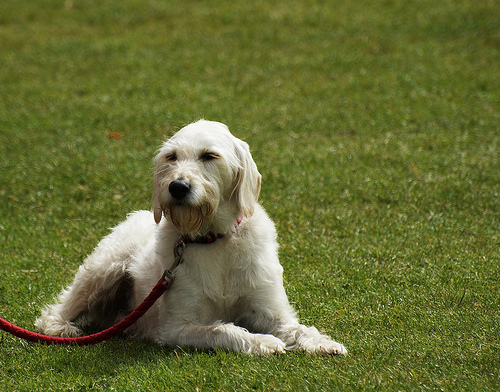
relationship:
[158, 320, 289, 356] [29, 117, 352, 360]
front leg of a dog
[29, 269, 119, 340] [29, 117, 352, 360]
back leg of a dog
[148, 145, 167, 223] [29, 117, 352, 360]
right ear of a dog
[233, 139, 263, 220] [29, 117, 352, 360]
left ear of a dog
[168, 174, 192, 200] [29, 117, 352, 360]
nose on front of dog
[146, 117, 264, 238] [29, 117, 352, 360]
head of a dog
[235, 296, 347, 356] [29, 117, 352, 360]
leg of a dog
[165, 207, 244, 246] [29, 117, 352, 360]
collar of a dog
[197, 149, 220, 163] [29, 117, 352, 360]
eye of a dog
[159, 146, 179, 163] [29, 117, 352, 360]
eye of a dog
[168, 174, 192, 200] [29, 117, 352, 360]
nose of a dog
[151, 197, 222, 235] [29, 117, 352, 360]
mouth of a dog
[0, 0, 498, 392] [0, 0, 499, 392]
field has grass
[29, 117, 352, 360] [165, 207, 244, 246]
dog has a collar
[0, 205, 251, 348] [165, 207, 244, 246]
leash attached to collar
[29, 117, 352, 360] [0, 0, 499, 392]
dog laying on grass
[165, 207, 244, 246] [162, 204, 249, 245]
collar tied around neck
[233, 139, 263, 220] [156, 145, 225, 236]
left ear laying down face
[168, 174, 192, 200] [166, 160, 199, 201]
nose on tip of snout